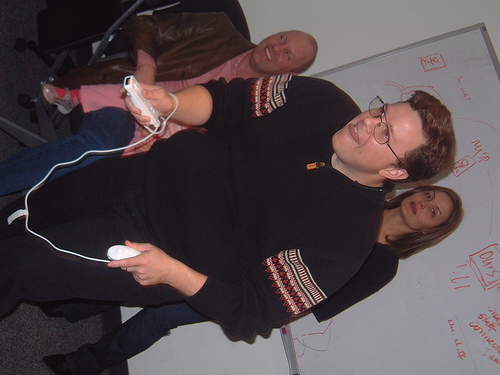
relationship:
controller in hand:
[88, 74, 200, 147] [148, 79, 197, 118]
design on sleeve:
[260, 255, 334, 309] [185, 251, 318, 332]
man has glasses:
[285, 87, 441, 212] [363, 94, 400, 164]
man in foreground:
[285, 87, 441, 212] [82, 84, 398, 281]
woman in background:
[396, 162, 463, 236] [378, 166, 497, 324]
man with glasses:
[285, 87, 441, 212] [363, 94, 400, 164]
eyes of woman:
[414, 185, 435, 218] [396, 162, 463, 236]